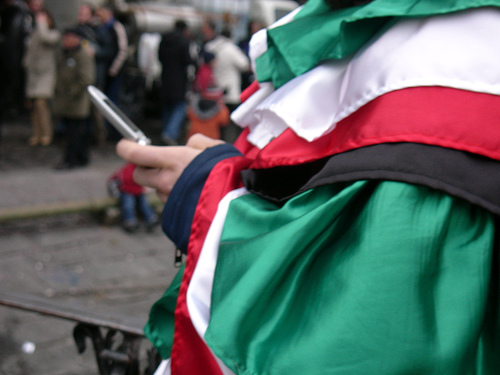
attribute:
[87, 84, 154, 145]
phone — silver, flip top, grey, plastic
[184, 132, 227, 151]
thumb — bent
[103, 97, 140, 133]
screen — dark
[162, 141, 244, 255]
sleeve — blue, navy blue, black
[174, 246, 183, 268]
zipper pull — metal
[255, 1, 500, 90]
fabric ruffle — green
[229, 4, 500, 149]
fabric ruffle — white, silky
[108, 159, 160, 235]
person — waiting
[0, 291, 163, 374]
railing — metal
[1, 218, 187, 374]
road — roughly paved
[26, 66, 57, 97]
skirt — light beige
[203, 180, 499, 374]
sleeve layer — green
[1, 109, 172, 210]
sidewalk — cement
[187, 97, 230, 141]
jacket — orange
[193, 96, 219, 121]
hood — grey, black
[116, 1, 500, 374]
person — making phone call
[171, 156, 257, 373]
sleeve layer — red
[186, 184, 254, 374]
sleeve layer — white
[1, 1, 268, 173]
crowd — blurry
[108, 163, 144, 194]
shirt — red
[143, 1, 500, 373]
clothing — multi-colored